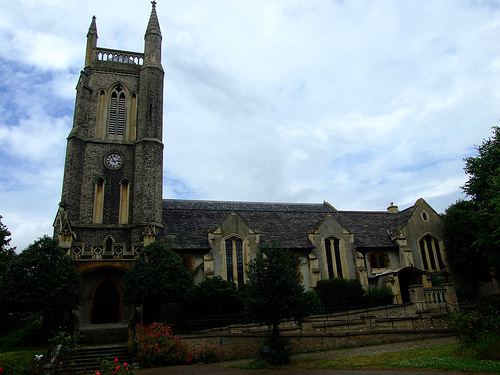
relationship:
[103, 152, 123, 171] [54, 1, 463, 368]
clock on building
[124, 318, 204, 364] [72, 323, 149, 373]
flowers near stairs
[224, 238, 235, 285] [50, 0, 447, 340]
window adorning building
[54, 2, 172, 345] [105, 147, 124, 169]
tower has a clock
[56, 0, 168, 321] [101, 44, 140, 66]
tower has a small dome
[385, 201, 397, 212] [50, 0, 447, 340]
chimney on a building